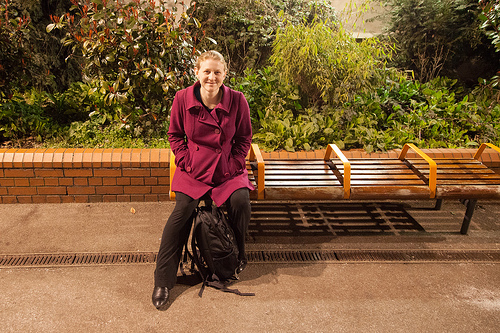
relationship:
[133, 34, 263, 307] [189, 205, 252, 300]
woman has a backpack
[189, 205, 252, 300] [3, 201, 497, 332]
backpack on ground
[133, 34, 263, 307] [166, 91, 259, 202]
woman wearing a jacket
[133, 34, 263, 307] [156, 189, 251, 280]
woman wearing pants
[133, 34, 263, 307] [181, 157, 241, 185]
woman has hands in her pockets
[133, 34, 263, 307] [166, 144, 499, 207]
woman sitting on a bench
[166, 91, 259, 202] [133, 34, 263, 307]
jacket on woman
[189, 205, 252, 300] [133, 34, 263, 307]
backpack next to woman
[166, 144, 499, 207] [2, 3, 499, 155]
bench near trees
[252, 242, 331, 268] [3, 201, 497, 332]
grate on ground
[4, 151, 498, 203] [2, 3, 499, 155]
wall near trees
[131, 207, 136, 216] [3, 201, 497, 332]
leaf on ground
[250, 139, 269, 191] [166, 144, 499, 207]
handle on bench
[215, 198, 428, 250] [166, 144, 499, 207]
shadow of a bench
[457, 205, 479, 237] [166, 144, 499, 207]
leg of a bench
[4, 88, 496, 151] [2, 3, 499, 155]
vegetation among trees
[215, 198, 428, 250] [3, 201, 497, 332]
shadow on ground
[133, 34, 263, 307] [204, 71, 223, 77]
woman has eyes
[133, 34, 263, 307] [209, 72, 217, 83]
woman has a nose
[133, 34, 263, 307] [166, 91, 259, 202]
woman in jacket